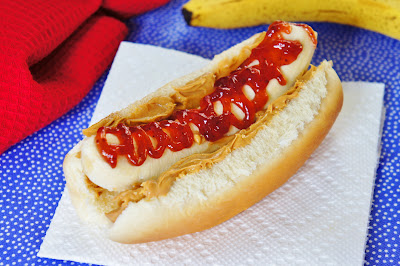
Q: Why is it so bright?
A: Day time.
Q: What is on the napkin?
A: A hotdog.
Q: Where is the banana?
A: Behind the hot dog.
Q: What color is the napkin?
A: White.